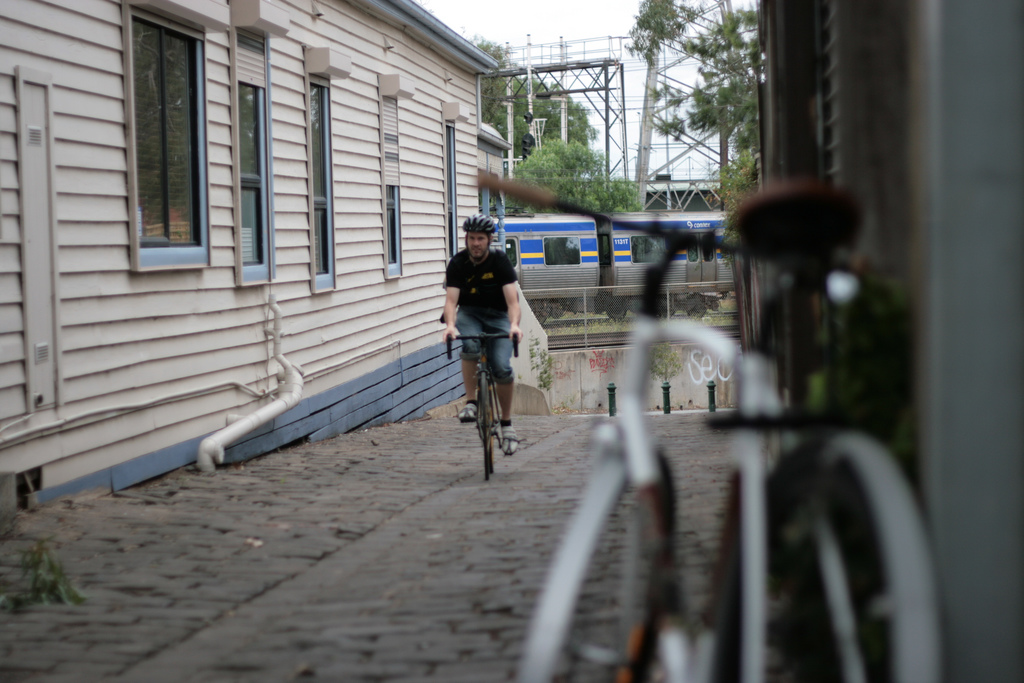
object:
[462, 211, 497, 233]
helmet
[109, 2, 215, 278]
window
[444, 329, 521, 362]
handlebars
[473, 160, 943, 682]
bike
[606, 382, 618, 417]
poles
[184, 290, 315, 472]
pipe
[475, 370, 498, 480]
front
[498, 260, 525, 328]
arm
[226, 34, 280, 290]
window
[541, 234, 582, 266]
window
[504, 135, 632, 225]
trees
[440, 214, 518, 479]
man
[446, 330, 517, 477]
bicycle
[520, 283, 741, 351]
fence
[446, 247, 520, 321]
shirt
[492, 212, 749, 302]
train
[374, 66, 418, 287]
windows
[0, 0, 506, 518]
building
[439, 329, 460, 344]
hands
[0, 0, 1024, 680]
cameral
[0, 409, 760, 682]
ground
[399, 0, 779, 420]
background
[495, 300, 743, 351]
tracks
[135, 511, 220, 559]
bricks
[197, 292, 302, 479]
water